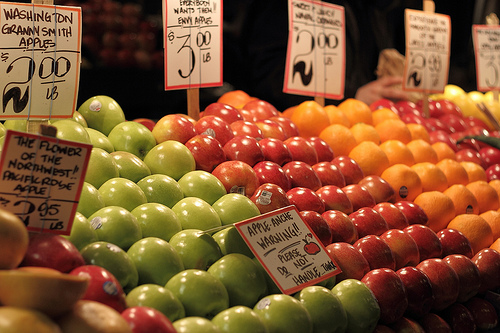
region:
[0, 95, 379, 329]
A display of green apples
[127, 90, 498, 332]
A display of red apples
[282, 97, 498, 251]
A display of oranges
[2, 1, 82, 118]
A paper price display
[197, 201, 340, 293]
A paper warning sign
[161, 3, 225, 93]
A three dollar per pound price sign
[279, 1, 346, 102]
A two dollar per pound price sign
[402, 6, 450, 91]
A two dollar ninty eight cent per pound price sign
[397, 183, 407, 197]
An oval fruit sticker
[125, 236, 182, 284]
A granny smith apple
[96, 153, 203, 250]
A pile of green apples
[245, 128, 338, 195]
A pile of red apples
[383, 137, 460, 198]
A pile of navel oranges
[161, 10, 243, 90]
A price sign for the red apples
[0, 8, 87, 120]
A $2.00 per pound sign for the green apples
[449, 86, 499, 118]
A pile of yellow bananas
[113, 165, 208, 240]
These are Washington Grammy Smith apples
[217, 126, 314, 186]
These red apples are fresh and shiny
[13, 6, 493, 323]
This is a fruit stand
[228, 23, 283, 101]
The back of this fruit stand is dark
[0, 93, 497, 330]
Apples on display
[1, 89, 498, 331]
Apples are on display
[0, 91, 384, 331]
Green apples on display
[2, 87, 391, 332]
Green apples are on display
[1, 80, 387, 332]
Granny smith apples on display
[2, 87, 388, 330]
Granny smith apples are on display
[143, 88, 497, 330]
Red apples on display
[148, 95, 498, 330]
Red apples are on display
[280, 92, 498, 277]
Oranges on display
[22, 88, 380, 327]
green granny smith apples for sale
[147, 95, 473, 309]
red gala apples for sale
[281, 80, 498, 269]
oranges for sale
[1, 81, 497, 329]
bundles of fruit organized by columns for sale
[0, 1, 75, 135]
sign with price above the apples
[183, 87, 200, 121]
wooden stick to hold up the sign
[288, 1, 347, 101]
the sign is handwritten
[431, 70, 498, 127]
bundle of lemons for sale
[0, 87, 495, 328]
fresh fruit for sale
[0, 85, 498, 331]
a variety of produce for sale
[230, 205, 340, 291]
red rimmed sign with an apple drawn on it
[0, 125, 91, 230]
red rimmed sign with word "flower" on it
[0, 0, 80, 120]
red rimmed sign with "granny" on it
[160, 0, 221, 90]
red rimmed sign with most expensive price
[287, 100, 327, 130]
an orange below a red rimmed sign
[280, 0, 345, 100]
red rimmed sign above the oranges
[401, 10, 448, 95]
red rimmed sign after the oranges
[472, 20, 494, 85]
the sign on the farthest right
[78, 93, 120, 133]
a green apple with a white sticker on it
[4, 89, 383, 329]
pile of green apples on display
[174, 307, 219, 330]
shiny green colored apple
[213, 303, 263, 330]
shiny green colored apple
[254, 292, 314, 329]
shiny green colored apple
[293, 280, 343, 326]
shiny green colored apple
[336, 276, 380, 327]
shiny green colored apple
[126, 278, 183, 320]
shiny green colored apple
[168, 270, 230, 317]
shiny green colored apple